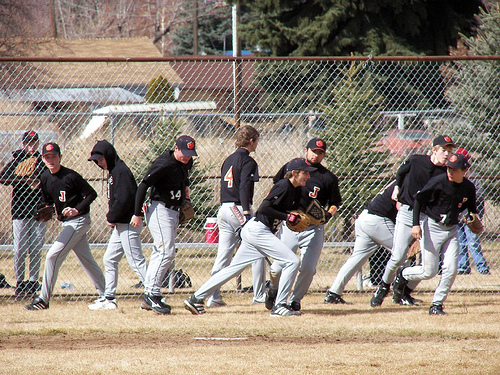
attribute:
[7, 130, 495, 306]
baseball players — in all white pants, male, in uniforms, in caps, holding mitts, standing outside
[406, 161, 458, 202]
black shirts — matching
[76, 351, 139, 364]
grass — brown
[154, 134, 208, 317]
black sneaker — white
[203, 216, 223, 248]
red cooler — for liquid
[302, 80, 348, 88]
fence — chain link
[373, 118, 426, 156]
red car — in back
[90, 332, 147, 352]
dirt — brown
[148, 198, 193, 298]
pants — white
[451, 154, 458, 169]
cap — for baseball